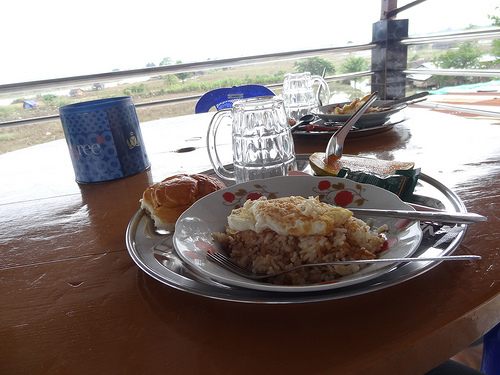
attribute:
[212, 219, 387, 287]
rice — browned, part of dish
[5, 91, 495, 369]
table — finished, shiny, wooden, brown, painted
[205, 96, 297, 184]
cup — transparent, upside down, glass, clear, a mug, mug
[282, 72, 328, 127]
cup — glass, clear, a mug, upside down, mug, transparent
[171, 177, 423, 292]
plate — floral, designed, ceramic, white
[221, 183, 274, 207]
roses — red, printed, painted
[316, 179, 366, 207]
roses — red, printed, painted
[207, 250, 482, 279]
fork — metal, silver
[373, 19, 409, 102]
post — reflective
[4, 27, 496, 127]
guardrail — surrounding balcony, metal, silver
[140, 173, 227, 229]
roll — dinner type, on the edge, sitting, topped, golden, white type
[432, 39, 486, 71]
tree — green, part of grouping, sparse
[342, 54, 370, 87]
tree — green, part of grouping, sparse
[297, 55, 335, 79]
tree — green, part of grouping, sparse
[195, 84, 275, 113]
chair — blue, showing top, plastic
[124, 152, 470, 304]
plate — tray, for serving, silver, a tray, second plate, larger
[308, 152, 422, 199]
fruit — cantaloupe, sliced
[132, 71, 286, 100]
bushes — green, in background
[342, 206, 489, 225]
knife — metal, silver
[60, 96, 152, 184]
container — blue, a canister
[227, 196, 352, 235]
topping — white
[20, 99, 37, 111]
tent — blue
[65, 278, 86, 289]
nick — out